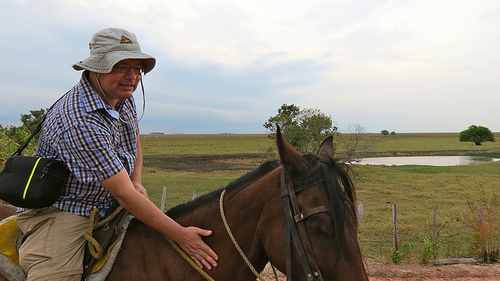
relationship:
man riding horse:
[16, 25, 222, 279] [1, 122, 375, 279]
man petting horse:
[16, 25, 222, 279] [1, 122, 375, 279]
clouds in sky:
[309, 17, 461, 101] [38, 2, 498, 114]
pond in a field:
[338, 148, 499, 171] [150, 116, 497, 190]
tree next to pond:
[452, 116, 494, 156] [338, 148, 499, 171]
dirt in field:
[385, 255, 422, 279] [6, 116, 496, 275]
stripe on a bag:
[18, 159, 49, 204] [4, 149, 71, 211]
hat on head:
[70, 22, 152, 76] [85, 44, 139, 110]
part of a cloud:
[229, 47, 260, 94] [146, 10, 473, 129]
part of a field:
[426, 164, 456, 203] [1, 131, 499, 280]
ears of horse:
[271, 124, 342, 169] [1, 122, 375, 279]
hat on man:
[70, 26, 161, 76] [16, 27, 221, 280]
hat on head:
[70, 26, 161, 76] [77, 30, 160, 120]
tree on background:
[457, 122, 494, 149] [5, 4, 484, 160]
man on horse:
[16, 25, 222, 279] [1, 122, 375, 279]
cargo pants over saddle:
[13, 205, 103, 279] [0, 200, 133, 279]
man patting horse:
[16, 25, 222, 279] [1, 122, 375, 279]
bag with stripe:
[5, 149, 76, 209] [21, 158, 44, 200]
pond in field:
[357, 116, 499, 197] [124, 110, 489, 273]